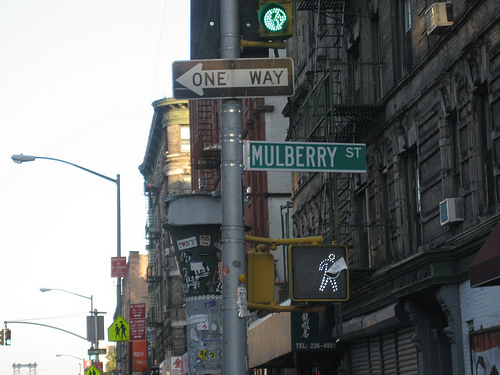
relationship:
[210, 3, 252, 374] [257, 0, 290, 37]
pole with traffic light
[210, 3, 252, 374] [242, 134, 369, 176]
pole with signs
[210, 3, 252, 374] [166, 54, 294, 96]
pole with traffic sign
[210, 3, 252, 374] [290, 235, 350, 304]
pole with traffic sign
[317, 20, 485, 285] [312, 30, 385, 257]
building with fire escape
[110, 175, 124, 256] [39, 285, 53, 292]
pole with street light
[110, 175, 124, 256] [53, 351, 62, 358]
pole with street light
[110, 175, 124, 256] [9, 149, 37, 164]
pole with street light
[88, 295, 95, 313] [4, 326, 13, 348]
pole with traffic light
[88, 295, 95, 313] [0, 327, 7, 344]
pole with traffic light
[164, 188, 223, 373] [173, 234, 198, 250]
structure filled with sticker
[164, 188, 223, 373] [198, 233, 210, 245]
structure filled with sticker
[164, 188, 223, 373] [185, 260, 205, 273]
structure filled with sticker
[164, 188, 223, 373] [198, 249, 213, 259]
structure filled with sticker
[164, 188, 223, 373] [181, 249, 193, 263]
structure filled with sticker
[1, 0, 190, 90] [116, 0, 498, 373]
blue sky to side of buildings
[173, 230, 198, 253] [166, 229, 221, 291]
sticker to side of metal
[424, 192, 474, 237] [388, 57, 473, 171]
air conditioner on wall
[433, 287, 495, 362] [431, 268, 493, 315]
paint on wall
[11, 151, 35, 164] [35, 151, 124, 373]
light on pole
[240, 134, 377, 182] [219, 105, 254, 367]
sign on pole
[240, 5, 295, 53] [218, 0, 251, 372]
yellow sign on gray pole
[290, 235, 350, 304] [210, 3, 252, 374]
traffic sign on pole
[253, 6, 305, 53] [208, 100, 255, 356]
traffic light on pole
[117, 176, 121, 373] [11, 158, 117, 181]
pole with street light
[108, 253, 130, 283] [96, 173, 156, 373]
red sign on pole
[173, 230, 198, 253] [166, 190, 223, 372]
sticker on post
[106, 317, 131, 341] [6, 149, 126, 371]
sign in pole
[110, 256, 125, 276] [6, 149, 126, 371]
sign in pole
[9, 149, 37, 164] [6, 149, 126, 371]
street light on a pole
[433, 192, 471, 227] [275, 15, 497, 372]
air conditioner sticking out of building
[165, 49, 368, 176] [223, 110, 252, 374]
signs are attached to pole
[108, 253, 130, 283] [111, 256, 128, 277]
red sign has white lettering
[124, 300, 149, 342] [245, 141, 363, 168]
red sign has white lettering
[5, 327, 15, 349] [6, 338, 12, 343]
signal showing light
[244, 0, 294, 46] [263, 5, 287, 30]
signal showing light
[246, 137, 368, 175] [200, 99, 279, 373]
green sign on gray pole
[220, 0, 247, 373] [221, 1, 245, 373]
sign on pole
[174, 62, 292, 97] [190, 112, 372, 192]
arrow on sign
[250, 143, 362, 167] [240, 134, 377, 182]
letters are on sign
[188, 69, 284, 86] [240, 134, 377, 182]
letters are on sign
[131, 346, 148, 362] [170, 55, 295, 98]
letters are on sign